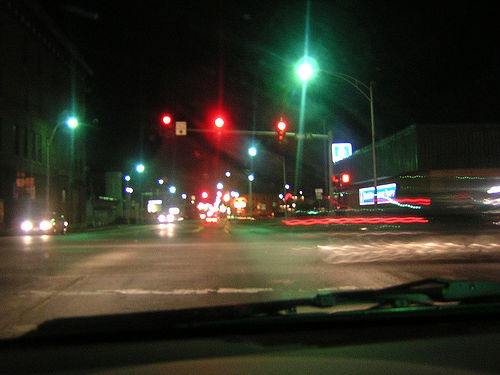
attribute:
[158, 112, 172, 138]
left traffic light — red, lit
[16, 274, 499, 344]
rain wiper — idle, black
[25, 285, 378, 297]
traffic line — white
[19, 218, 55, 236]
headlights — bright, on, lit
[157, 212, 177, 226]
headlights — bright, on, lit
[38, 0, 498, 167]
sky — dark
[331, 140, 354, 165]
lit sign — blue, white, electric, distant, neon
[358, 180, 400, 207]
wall sign — blue, electric, neon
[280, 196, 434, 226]
brake light streak — blurry, blurred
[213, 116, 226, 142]
middle traffic light — red, lit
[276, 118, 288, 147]
right traffic light — red, lit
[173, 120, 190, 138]
traffic sign — white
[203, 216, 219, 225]
tail lights — distant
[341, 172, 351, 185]
pedestrian light — red, lit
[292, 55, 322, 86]
street light — lit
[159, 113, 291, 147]
traffic lights — glowing, lit, red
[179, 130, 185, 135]
circle — green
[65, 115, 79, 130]
street light — first